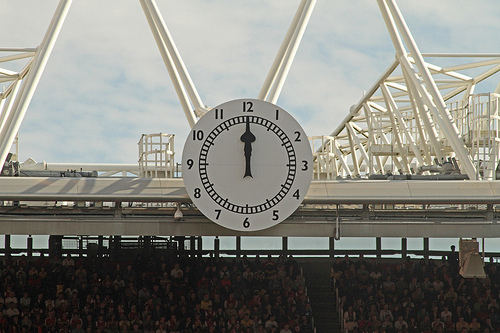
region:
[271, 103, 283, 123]
black number on a clock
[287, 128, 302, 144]
black number on a clock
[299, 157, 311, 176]
black number on a clock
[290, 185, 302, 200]
black number on a clock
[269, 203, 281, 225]
black number on a clock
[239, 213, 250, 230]
black number on a clock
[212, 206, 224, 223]
black number on a clock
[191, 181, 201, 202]
black number on a clock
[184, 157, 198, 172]
black number on a clock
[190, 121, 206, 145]
black number on a clock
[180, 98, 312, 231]
the face of a clock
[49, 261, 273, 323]
people in the seating area of a stadium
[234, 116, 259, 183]
the hand of a clock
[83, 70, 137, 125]
white clouds in the sky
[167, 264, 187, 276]
a person in a white shirt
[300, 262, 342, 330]
the stairs in a stadium seating area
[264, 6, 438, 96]
white metal spires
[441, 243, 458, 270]
a person that is standing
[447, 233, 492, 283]
a suspended light in a stadium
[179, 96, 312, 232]
The clock is white and black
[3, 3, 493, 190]
The metal structure is white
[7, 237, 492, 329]
People in the stands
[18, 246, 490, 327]
The people are sitting down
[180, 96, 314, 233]
The clock says 12:00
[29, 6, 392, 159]
The sky is cloudy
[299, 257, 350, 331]
The stairs are grey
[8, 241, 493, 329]
The people are in the shade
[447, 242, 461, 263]
The person is standing next to the pole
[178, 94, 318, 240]
The clock is attached to the metal structure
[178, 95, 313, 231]
a huge white clock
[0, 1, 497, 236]
a white clock attached to the beams of a stadium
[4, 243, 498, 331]
people in the stands at a stadium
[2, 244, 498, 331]
people inside a stadium at an event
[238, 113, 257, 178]
black hour and minute hands on the clock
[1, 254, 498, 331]
patrons inside a stadiumd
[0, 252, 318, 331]
people sitting down in the stands of a stadium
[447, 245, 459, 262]
a man standing inside a stadium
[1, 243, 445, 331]
people in the stands watching an event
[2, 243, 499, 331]
people attending an event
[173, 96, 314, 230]
clock shows 12:00 noon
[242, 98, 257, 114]
number 12 on the clock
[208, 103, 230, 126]
number 11 on the clock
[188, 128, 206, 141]
number 10 on the clock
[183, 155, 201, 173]
number 9 on the clock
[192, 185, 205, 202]
number 8 on the clock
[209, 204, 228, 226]
number 7 on the clock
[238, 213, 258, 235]
number 6 on the clock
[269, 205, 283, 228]
number 5 on the clock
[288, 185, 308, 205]
number 4 on the clock